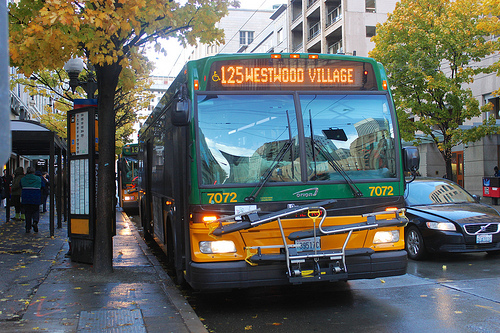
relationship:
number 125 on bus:
[220, 64, 245, 87] [138, 53, 410, 286]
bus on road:
[138, 53, 410, 286] [418, 255, 489, 331]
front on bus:
[187, 51, 406, 286] [138, 53, 410, 286]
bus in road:
[138, 53, 410, 286] [418, 255, 489, 331]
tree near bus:
[392, 18, 478, 128] [138, 53, 410, 286]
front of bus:
[187, 51, 406, 286] [138, 53, 410, 286]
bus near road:
[138, 53, 410, 286] [418, 255, 489, 331]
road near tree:
[418, 255, 489, 331] [392, 18, 478, 128]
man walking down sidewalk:
[13, 153, 52, 239] [2, 211, 141, 325]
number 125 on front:
[220, 64, 245, 87] [187, 51, 406, 286]